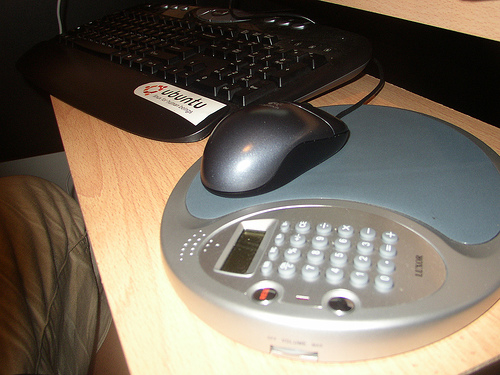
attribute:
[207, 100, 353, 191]
computer mouse — Blue, black, wired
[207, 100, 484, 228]
mouse pad — Blue, gray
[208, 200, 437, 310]
calculator — gray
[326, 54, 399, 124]
cable — Black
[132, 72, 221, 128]
sticker — Red, white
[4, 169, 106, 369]
shorts — tan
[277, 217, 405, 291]
keypad — soft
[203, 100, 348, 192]
mouse — shiny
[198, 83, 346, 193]
mouse — shiny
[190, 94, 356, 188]
mouse — shiny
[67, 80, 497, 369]
keyboard desk shelf — brown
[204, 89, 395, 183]
mouse on desk — silver, black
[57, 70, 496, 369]
computer desk — wooden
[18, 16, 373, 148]
computer keyboard — black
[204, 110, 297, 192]
mouse — shiny